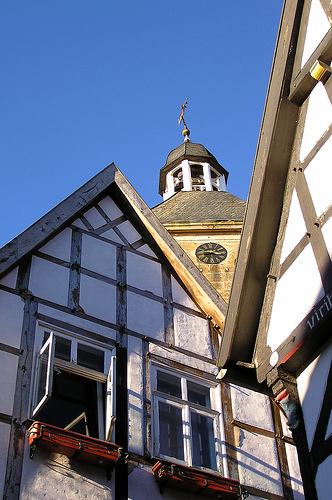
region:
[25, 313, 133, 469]
one window is open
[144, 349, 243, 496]
one window is closed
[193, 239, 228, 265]
clock is round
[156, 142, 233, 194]
bell is on rooftop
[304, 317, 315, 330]
v is on the wood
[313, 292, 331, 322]
iril is on the wood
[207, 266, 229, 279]
building is made of brick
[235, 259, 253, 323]
trimming of house is brown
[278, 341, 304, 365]
red paint on trimming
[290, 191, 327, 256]
building is brown and white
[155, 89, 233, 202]
white tower with weather vane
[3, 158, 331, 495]
white Tudor style building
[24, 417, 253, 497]
red flower boxes under windows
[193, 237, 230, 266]
black clock in brick building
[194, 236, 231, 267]
black clock face with gold numerals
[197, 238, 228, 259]
time reads 2:45 p.m.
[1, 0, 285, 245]
clear bright blue cloudless sky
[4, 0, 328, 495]
this is an outdoor city street scene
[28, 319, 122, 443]
open window in white building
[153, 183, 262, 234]
sloping grey roof above clock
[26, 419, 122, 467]
Red plant box outside the window on the left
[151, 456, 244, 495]
Red plant box outside the window on the right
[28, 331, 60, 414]
Open window jutting out from the window on the left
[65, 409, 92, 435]
Window on the inside forming a triangle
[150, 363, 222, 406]
Upper two small square windows next to each other on the right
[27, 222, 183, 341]
Black and white squares on the building above the windows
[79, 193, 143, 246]
Three diamonds at the roof of the building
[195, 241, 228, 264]
Round clock in brick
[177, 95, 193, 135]
Gold adornment pointing up towards the sky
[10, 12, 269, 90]
Clear blue sky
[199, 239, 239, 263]
Clock on a building.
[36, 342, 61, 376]
The window is open.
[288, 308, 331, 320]
Writing on the building.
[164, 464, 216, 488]
Plant boxes under the window.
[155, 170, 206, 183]
Bell tower on top of building.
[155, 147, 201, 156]
Roof of bell tower is black.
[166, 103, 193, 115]
Wind compass on top of building.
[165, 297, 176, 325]
Black grout on the building.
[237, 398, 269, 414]
The tiles are white.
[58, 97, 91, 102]
The sky is blue.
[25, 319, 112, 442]
Window on a building that is open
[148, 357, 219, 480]
Window on a building that is shut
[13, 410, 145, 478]
Red planter box below a window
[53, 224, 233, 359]
White and brown building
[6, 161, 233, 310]
Brown roof on a building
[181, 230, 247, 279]
Clock on a tower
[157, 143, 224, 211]
White and brown tower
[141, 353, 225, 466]
White window frame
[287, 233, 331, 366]
Brown lines on a white building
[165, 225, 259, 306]
Brown brick clock tower